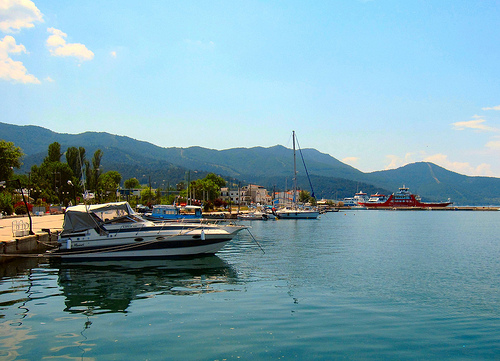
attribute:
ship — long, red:
[335, 175, 485, 237]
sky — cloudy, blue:
[13, 0, 486, 195]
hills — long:
[67, 115, 414, 245]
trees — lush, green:
[25, 136, 196, 218]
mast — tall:
[282, 123, 322, 188]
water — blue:
[135, 220, 447, 349]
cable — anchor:
[213, 204, 292, 244]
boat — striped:
[58, 190, 232, 275]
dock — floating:
[9, 208, 83, 254]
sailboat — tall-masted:
[246, 123, 325, 201]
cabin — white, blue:
[127, 185, 207, 218]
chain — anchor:
[196, 223, 296, 278]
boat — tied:
[50, 205, 220, 254]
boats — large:
[55, 193, 247, 274]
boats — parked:
[45, 201, 236, 258]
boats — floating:
[62, 199, 237, 316]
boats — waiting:
[70, 190, 250, 282]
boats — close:
[43, 180, 243, 261]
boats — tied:
[70, 186, 365, 302]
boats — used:
[21, 175, 338, 269]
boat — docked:
[42, 197, 252, 267]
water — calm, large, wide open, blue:
[12, 210, 494, 355]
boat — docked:
[46, 191, 251, 269]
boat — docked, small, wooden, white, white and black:
[48, 200, 250, 259]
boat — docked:
[48, 200, 230, 262]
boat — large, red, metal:
[359, 193, 450, 208]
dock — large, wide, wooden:
[2, 213, 61, 253]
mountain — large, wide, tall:
[366, 163, 499, 202]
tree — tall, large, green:
[0, 139, 23, 184]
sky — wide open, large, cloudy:
[0, 0, 500, 180]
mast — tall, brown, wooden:
[291, 130, 296, 209]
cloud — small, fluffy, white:
[47, 28, 93, 61]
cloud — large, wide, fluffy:
[0, 0, 46, 32]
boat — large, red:
[354, 189, 454, 209]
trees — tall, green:
[0, 141, 139, 202]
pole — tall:
[293, 131, 296, 204]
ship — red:
[356, 188, 447, 208]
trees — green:
[8, 146, 164, 206]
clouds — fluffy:
[5, 3, 96, 96]